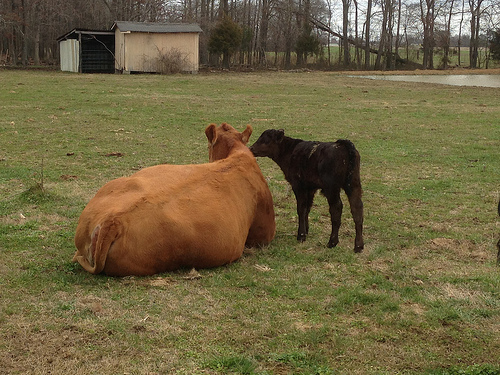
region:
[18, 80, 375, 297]
a cow and a calf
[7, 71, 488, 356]
a cow and a calf in a pasture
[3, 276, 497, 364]
brown and green grass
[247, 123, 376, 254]
a black calf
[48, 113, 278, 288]
a brown cow lying on the ground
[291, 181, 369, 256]
the legs of a calf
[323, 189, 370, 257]
the rear legs of a calf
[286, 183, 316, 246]
the front legs of a calf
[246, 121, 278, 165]
the head of a calf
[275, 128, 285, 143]
the ear of a calf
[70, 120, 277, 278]
large brown cow laying down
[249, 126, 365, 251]
small black baby calf standing next to big cow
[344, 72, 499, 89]
small pond in the background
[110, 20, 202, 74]
small brown building with black roof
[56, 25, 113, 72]
small metal open shed coming off of the small building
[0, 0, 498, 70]
row of trees in the background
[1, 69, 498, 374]
green and brown grass the cows are on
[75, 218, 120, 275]
big brown cow's curled tail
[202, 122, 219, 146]
big brown cow's left ear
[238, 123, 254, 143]
big brown cow's right ear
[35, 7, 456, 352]
The cows are on a farm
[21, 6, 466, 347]
A cow is laying in the grass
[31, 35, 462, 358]
A mother cow and her calf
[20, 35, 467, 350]
A calf is licking its mother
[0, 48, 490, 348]
The cows are very peaceful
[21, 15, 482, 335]
The cows are out in the daytime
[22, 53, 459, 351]
The cows are enjoying their day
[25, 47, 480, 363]
The cows are out in the sunshine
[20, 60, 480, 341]
Two cows are waiting to be fed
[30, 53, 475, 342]
A baby cow wants some milk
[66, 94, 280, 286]
an adult laying in the grass field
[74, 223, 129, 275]
the tail curled on the ground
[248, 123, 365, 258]
the black calf standing up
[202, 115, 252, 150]
the ears of the brown cow sticking up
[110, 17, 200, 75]
the shed in the field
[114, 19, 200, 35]
the grey roof on the shed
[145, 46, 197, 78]
the bare bush next to the shed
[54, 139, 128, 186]
the dirt patches in the grass field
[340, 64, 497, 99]
a pool of water by the tree line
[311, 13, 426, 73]
the tree fallen over in the forrest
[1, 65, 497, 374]
A field of green and brown grass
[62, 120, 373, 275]
Two cows in a field together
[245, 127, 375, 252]
A black baby calf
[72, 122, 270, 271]
A brown mother cow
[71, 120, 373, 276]
A black calf standing beside its mother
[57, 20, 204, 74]
Two sheds across the field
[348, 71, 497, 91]
A calm body of water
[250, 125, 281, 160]
The head of a black calf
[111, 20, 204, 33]
The gray shed roof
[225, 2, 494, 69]
A line of trees across the yard